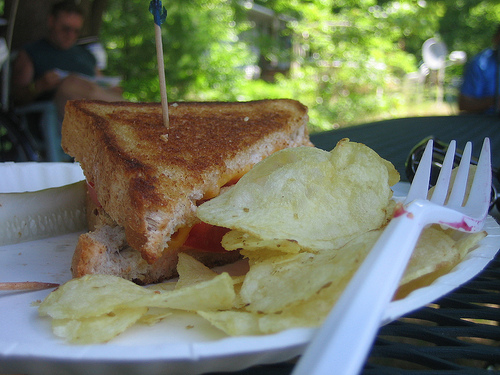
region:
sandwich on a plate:
[72, 83, 313, 208]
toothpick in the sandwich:
[140, 7, 188, 131]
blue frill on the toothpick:
[142, 6, 178, 30]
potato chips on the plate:
[209, 151, 375, 294]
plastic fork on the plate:
[309, 145, 486, 370]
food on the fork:
[440, 203, 479, 244]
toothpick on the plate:
[7, 269, 53, 299]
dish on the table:
[1, 153, 81, 228]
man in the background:
[30, 10, 112, 110]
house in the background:
[247, 4, 289, 68]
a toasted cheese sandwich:
[61, 96, 199, 273]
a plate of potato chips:
[201, 138, 396, 241]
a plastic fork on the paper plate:
[395, 132, 499, 374]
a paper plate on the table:
[1, 334, 323, 370]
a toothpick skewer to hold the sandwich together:
[151, 0, 172, 134]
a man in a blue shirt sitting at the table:
[458, 23, 499, 115]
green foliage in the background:
[164, 1, 460, 97]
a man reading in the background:
[1, 1, 126, 103]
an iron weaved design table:
[388, 320, 499, 373]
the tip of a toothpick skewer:
[0, 278, 60, 293]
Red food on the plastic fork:
[388, 198, 483, 234]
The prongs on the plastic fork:
[406, 136, 490, 211]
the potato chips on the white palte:
[201, 138, 487, 325]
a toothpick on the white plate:
[0, 271, 60, 296]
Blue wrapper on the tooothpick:
[148, 0, 168, 26]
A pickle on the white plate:
[0, 178, 85, 235]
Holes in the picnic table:
[408, 311, 498, 374]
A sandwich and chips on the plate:
[37, 101, 499, 333]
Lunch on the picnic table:
[3, 1, 499, 368]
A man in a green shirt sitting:
[5, 6, 121, 161]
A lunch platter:
[37, 0, 450, 330]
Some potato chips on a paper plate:
[176, 181, 373, 327]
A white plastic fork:
[336, 177, 477, 372]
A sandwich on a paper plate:
[96, 81, 242, 267]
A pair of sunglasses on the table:
[420, 123, 489, 213]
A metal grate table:
[383, 316, 484, 362]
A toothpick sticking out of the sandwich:
[148, 42, 181, 133]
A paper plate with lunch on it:
[13, 338, 216, 365]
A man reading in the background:
[19, 35, 124, 99]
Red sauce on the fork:
[420, 209, 477, 241]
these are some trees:
[185, 14, 391, 92]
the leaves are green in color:
[177, 8, 220, 67]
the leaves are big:
[182, 12, 236, 71]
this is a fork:
[291, 134, 494, 374]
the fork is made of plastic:
[416, 197, 432, 217]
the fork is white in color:
[416, 180, 441, 198]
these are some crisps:
[224, 184, 312, 309]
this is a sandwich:
[47, 94, 312, 266]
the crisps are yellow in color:
[263, 180, 303, 210]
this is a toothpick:
[143, 5, 199, 135]